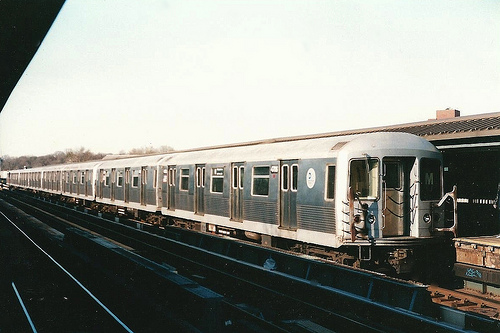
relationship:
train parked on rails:
[0, 130, 466, 263] [0, 183, 499, 333]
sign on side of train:
[303, 163, 318, 192] [0, 130, 466, 263]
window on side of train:
[245, 162, 278, 197] [0, 130, 466, 263]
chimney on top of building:
[433, 103, 465, 124] [92, 100, 496, 308]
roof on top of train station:
[147, 109, 500, 153] [134, 104, 497, 278]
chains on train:
[339, 199, 378, 236] [0, 130, 466, 263]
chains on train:
[382, 178, 419, 218] [0, 130, 466, 263]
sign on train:
[303, 163, 318, 192] [0, 130, 466, 263]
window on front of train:
[349, 156, 380, 201] [13, 117, 462, 283]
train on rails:
[0, 130, 466, 263] [0, 183, 499, 333]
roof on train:
[5, 132, 437, 166] [0, 130, 466, 263]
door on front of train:
[368, 155, 407, 240] [13, 117, 462, 283]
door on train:
[277, 157, 299, 234] [52, 101, 487, 331]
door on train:
[281, 157, 297, 234] [0, 130, 466, 263]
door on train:
[227, 159, 248, 222] [0, 130, 466, 263]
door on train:
[192, 162, 207, 212] [0, 130, 466, 263]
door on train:
[167, 165, 178, 207] [0, 130, 466, 263]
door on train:
[138, 163, 147, 205] [0, 130, 466, 263]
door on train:
[124, 161, 129, 200] [0, 130, 466, 263]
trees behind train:
[3, 146, 175, 171] [13, 117, 462, 283]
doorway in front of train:
[368, 147, 449, 263] [42, 122, 479, 299]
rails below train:
[14, 185, 499, 327] [0, 130, 466, 263]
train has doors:
[28, 82, 493, 255] [224, 151, 304, 235]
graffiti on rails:
[459, 254, 499, 287] [0, 183, 499, 333]